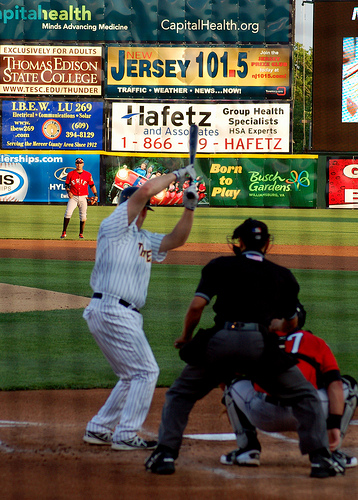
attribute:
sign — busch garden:
[226, 157, 296, 201]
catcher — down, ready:
[298, 314, 344, 377]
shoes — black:
[331, 449, 357, 466]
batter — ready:
[81, 163, 205, 450]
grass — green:
[1, 203, 356, 390]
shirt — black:
[64, 161, 170, 315]